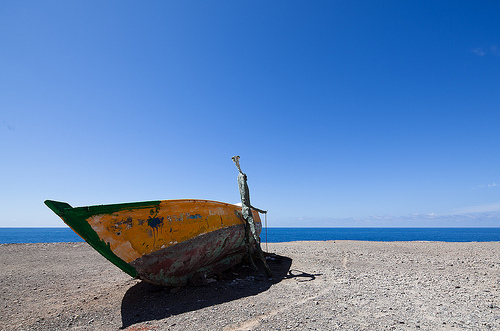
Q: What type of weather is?
A: It is clear.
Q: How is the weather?
A: It is clear.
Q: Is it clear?
A: Yes, it is clear.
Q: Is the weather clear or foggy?
A: It is clear.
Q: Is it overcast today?
A: No, it is clear.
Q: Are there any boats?
A: Yes, there is a boat.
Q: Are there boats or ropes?
A: Yes, there is a boat.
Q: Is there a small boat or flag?
A: Yes, there is a small boat.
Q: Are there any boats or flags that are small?
A: Yes, the boat is small.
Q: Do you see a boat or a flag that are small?
A: Yes, the boat is small.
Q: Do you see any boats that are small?
A: Yes, there is a small boat.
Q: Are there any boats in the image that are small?
A: Yes, there is a boat that is small.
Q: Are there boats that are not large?
A: Yes, there is a small boat.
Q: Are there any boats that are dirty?
A: Yes, there is a dirty boat.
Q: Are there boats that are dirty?
A: Yes, there is a boat that is dirty.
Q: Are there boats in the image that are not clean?
A: Yes, there is a dirty boat.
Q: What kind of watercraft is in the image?
A: The watercraft is a boat.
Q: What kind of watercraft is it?
A: The watercraft is a boat.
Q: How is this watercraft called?
A: This is a boat.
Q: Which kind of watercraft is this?
A: This is a boat.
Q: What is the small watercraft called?
A: The watercraft is a boat.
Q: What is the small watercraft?
A: The watercraft is a boat.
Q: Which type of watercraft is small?
A: The watercraft is a boat.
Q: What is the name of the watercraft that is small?
A: The watercraft is a boat.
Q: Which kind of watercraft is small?
A: The watercraft is a boat.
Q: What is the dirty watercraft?
A: The watercraft is a boat.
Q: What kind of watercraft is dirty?
A: The watercraft is a boat.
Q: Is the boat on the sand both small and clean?
A: No, the boat is small but dirty.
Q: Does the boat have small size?
A: Yes, the boat is small.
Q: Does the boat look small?
A: Yes, the boat is small.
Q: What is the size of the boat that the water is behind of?
A: The boat is small.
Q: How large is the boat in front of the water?
A: The boat is small.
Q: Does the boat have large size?
A: No, the boat is small.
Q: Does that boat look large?
A: No, the boat is small.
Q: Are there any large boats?
A: No, there is a boat but it is small.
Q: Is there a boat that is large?
A: No, there is a boat but it is small.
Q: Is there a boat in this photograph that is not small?
A: No, there is a boat but it is small.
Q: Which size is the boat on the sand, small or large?
A: The boat is small.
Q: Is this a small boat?
A: Yes, this is a small boat.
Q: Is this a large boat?
A: No, this is a small boat.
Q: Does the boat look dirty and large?
A: No, the boat is dirty but small.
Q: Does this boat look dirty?
A: Yes, the boat is dirty.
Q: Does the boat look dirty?
A: Yes, the boat is dirty.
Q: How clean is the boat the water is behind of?
A: The boat is dirty.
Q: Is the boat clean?
A: No, the boat is dirty.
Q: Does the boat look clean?
A: No, the boat is dirty.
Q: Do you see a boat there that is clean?
A: No, there is a boat but it is dirty.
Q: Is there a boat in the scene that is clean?
A: No, there is a boat but it is dirty.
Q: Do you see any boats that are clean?
A: No, there is a boat but it is dirty.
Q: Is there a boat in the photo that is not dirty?
A: No, there is a boat but it is dirty.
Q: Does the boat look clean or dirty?
A: The boat is dirty.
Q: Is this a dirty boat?
A: Yes, this is a dirty boat.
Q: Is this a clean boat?
A: No, this is a dirty boat.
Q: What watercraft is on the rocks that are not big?
A: The watercraft is a boat.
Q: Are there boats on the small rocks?
A: Yes, there is a boat on the rocks.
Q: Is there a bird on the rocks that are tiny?
A: No, there is a boat on the rocks.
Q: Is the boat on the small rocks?
A: Yes, the boat is on the rocks.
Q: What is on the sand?
A: The boat is on the sand.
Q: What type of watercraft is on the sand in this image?
A: The watercraft is a boat.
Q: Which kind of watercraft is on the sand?
A: The watercraft is a boat.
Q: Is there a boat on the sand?
A: Yes, there is a boat on the sand.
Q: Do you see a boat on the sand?
A: Yes, there is a boat on the sand.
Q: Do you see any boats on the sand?
A: Yes, there is a boat on the sand.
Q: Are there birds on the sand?
A: No, there is a boat on the sand.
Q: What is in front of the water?
A: The boat is in front of the water.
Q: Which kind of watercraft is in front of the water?
A: The watercraft is a boat.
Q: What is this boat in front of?
A: The boat is in front of the water.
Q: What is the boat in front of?
A: The boat is in front of the water.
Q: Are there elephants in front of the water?
A: No, there is a boat in front of the water.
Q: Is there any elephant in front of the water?
A: No, there is a boat in front of the water.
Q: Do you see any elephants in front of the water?
A: No, there is a boat in front of the water.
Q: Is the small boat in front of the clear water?
A: Yes, the boat is in front of the water.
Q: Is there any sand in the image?
A: Yes, there is sand.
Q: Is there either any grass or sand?
A: Yes, there is sand.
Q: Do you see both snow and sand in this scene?
A: No, there is sand but no snow.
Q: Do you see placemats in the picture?
A: No, there are no placemats.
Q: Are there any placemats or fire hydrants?
A: No, there are no placemats or fire hydrants.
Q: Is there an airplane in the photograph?
A: No, there are no airplanes.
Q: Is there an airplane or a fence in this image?
A: No, there are no airplanes or fences.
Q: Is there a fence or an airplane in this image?
A: No, there are no airplanes or fences.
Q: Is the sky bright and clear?
A: Yes, the sky is bright and clear.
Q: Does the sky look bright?
A: Yes, the sky is bright.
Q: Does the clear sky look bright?
A: Yes, the sky is bright.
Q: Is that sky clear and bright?
A: Yes, the sky is clear and bright.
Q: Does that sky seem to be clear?
A: Yes, the sky is clear.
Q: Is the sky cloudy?
A: No, the sky is clear.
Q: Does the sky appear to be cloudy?
A: No, the sky is clear.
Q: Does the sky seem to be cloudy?
A: No, the sky is clear.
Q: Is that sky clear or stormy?
A: The sky is clear.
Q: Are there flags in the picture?
A: No, there are no flags.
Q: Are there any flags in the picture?
A: No, there are no flags.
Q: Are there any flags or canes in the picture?
A: No, there are no flags or canes.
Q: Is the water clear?
A: Yes, the water is clear.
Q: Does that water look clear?
A: Yes, the water is clear.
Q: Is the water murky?
A: No, the water is clear.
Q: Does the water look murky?
A: No, the water is clear.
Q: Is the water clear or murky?
A: The water is clear.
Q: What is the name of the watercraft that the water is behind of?
A: The watercraft is a boat.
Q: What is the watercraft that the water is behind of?
A: The watercraft is a boat.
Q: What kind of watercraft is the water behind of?
A: The water is behind the boat.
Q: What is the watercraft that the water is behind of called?
A: The watercraft is a boat.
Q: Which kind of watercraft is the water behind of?
A: The water is behind the boat.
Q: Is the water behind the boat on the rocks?
A: Yes, the water is behind the boat.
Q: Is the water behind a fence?
A: No, the water is behind the boat.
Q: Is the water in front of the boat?
A: No, the water is behind the boat.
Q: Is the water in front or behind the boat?
A: The water is behind the boat.